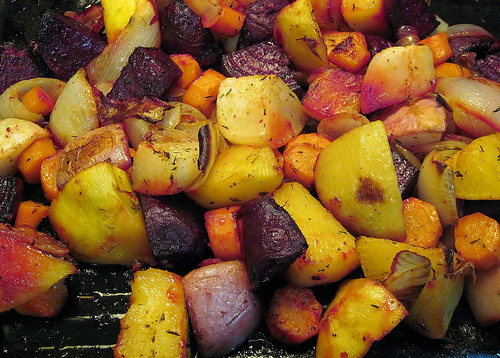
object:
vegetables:
[122, 97, 214, 145]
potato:
[272, 181, 361, 285]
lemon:
[317, 117, 409, 237]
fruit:
[357, 41, 444, 115]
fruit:
[1, 229, 85, 322]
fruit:
[449, 205, 500, 271]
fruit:
[178, 62, 226, 112]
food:
[129, 268, 182, 355]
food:
[237, 191, 309, 293]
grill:
[31, 260, 127, 357]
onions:
[0, 37, 50, 93]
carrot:
[167, 50, 201, 89]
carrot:
[181, 64, 227, 117]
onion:
[79, 16, 170, 90]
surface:
[115, 277, 172, 358]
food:
[47, 158, 160, 279]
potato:
[213, 72, 304, 148]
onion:
[177, 259, 267, 358]